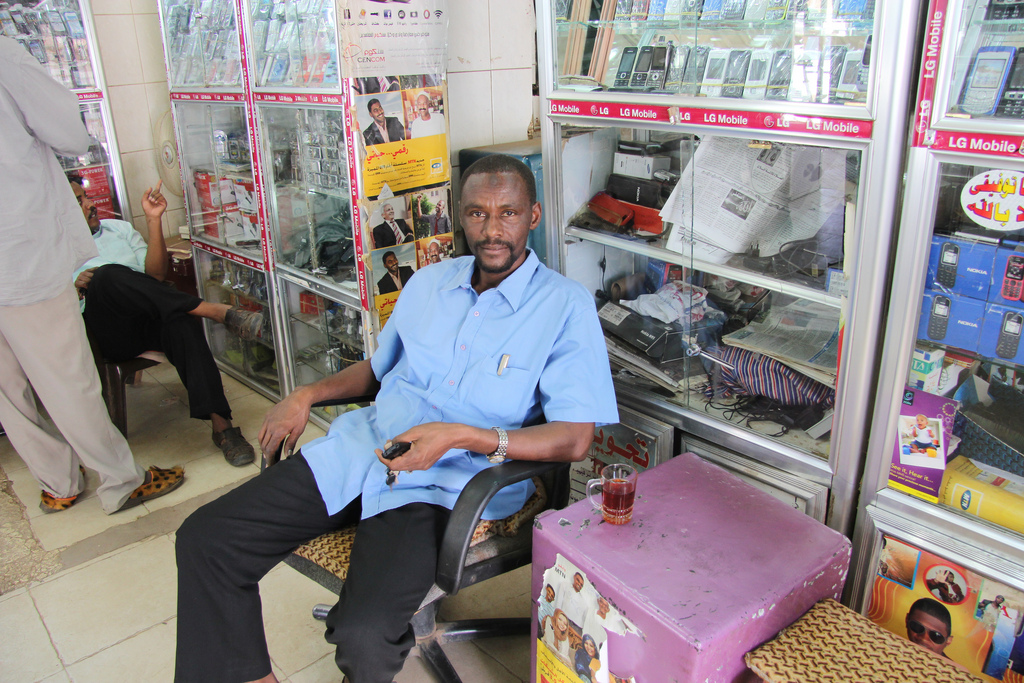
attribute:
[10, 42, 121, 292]
shirt — long , beige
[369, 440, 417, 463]
cell — black 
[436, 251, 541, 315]
collar — Blue 